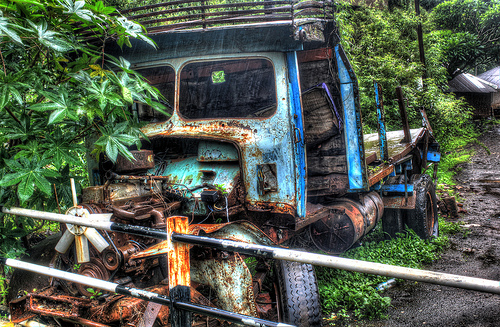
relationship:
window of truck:
[179, 61, 275, 113] [98, 45, 430, 235]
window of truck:
[110, 65, 170, 119] [98, 45, 430, 235]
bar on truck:
[0, 206, 500, 325] [1, 0, 443, 325]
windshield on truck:
[174, 58, 274, 117] [1, 0, 443, 325]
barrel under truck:
[307, 191, 385, 253] [213, 128, 442, 249]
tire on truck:
[269, 245, 319, 327] [57, 26, 440, 318]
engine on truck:
[56, 153, 233, 258] [116, 20, 394, 250]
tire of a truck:
[269, 245, 319, 327] [1, 0, 443, 325]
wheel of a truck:
[406, 172, 441, 238] [1, 0, 443, 325]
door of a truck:
[286, 56, 362, 208] [26, 10, 456, 323]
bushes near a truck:
[0, 2, 172, 201] [130, 3, 444, 319]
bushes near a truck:
[346, 7, 496, 129] [130, 3, 444, 319]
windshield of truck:
[124, 61, 182, 124] [1, 0, 443, 325]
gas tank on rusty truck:
[315, 192, 384, 254] [73, 5, 440, 320]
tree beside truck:
[14, 20, 139, 195] [28, 6, 408, 318]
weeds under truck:
[327, 223, 433, 310] [1, 0, 443, 325]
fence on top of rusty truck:
[65, 1, 335, 48] [8, 5, 439, 327]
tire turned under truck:
[269, 245, 319, 327] [54, 3, 473, 322]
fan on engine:
[47, 184, 115, 261] [87, 182, 178, 252]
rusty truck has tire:
[8, 5, 439, 327] [269, 245, 319, 324]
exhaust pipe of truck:
[312, 208, 368, 243] [1, 0, 443, 325]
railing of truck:
[83, 7, 345, 31] [67, 21, 451, 266]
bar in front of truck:
[8, 198, 478, 325] [33, 20, 433, 306]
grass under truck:
[322, 235, 409, 304] [1, 0, 443, 325]